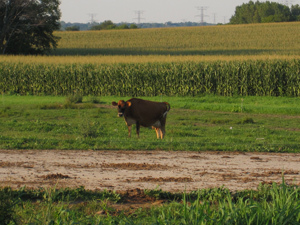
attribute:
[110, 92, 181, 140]
cow — watching, looking, close, white, brown, standing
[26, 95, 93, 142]
grass — here, green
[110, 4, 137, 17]
sky — above, high, blue, here, close, white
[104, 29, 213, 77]
field — below, massive, close, here, green, large, big, yellow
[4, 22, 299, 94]
crops — tall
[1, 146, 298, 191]
path — muddy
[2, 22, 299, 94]
field — large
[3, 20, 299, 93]
corn — green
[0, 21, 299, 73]
tassels — yellow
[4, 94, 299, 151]
grass — short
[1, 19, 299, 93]
plants — green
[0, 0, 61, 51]
leaves — green